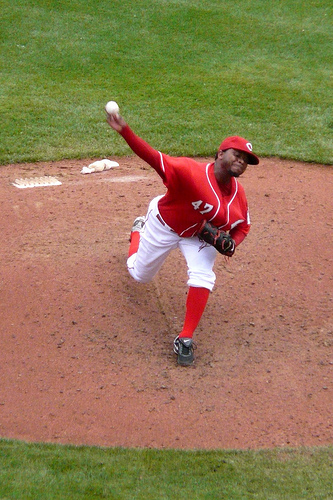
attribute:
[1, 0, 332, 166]
grass — short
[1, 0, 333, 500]
ground — existing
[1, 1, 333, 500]
field — existing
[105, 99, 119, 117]
ball — round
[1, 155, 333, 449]
pitcher's mound — dirt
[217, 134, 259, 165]
baseball cap — red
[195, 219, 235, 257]
baseball glove — black, red, leather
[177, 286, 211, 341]
sock — red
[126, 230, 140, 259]
sock — red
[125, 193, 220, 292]
pants — short, white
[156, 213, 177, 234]
cloth belt — red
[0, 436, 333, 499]
grass — green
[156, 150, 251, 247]
top — red, long sleeve